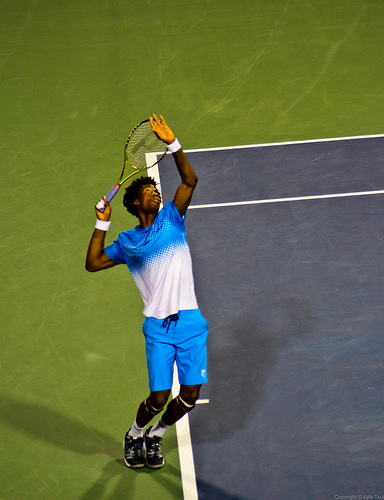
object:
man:
[84, 110, 213, 471]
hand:
[147, 112, 174, 143]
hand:
[93, 192, 112, 223]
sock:
[126, 415, 146, 440]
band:
[166, 136, 182, 156]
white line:
[172, 357, 203, 499]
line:
[185, 185, 384, 213]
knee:
[186, 385, 202, 407]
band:
[94, 218, 111, 231]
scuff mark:
[155, 130, 383, 158]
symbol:
[200, 368, 206, 378]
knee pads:
[142, 393, 166, 418]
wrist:
[94, 218, 109, 236]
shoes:
[122, 425, 146, 471]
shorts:
[141, 307, 210, 393]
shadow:
[1, 382, 130, 469]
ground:
[2, 2, 384, 499]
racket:
[94, 117, 169, 215]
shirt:
[102, 196, 199, 321]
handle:
[94, 182, 121, 215]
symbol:
[125, 438, 134, 445]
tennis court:
[0, 0, 383, 499]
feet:
[122, 424, 147, 470]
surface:
[0, 0, 383, 499]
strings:
[162, 313, 180, 335]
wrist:
[166, 141, 181, 155]